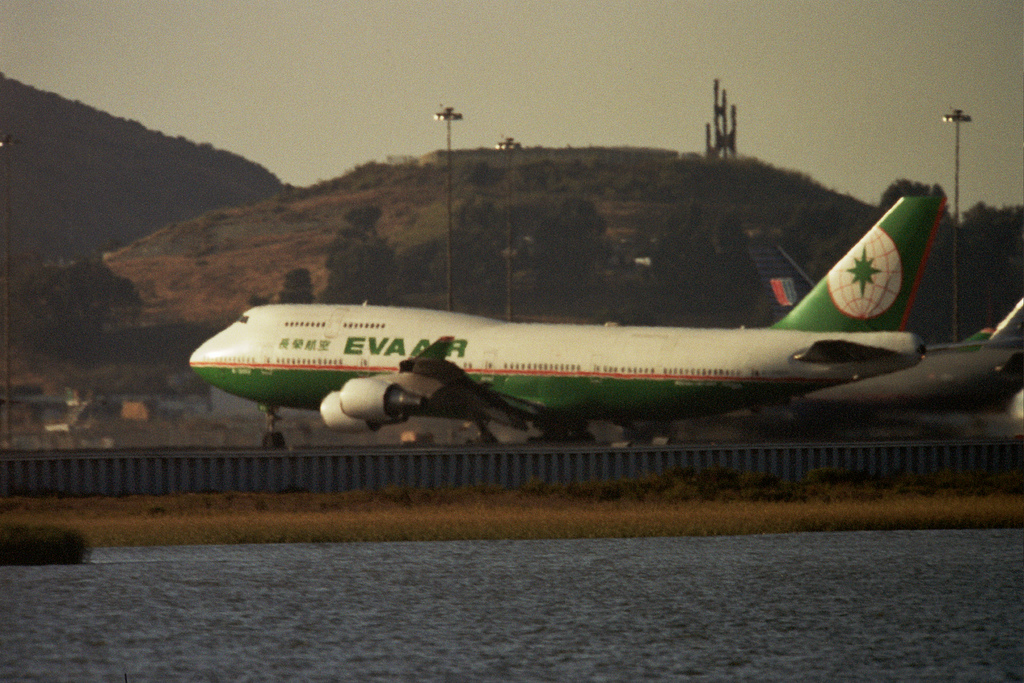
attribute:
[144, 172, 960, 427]
plane — white, green, red, lit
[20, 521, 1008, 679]
water — gray, still, wavy, blue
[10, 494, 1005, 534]
grass — brown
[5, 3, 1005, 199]
sky — hazy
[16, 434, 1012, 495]
gate — gray